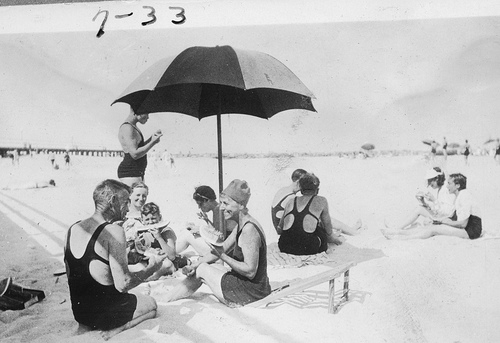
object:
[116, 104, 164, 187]
person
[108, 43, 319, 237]
umbrella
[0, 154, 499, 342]
sand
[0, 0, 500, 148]
sky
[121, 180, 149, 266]
woman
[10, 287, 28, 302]
black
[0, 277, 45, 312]
cloth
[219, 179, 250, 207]
cap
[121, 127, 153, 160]
arm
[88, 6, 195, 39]
date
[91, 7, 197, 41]
ink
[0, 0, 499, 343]
photo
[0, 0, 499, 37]
border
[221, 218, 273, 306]
suit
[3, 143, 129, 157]
pier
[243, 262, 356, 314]
chair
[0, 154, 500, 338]
ground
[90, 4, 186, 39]
writing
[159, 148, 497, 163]
swimming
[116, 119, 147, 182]
costume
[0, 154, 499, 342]
sandy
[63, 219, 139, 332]
suits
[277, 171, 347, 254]
women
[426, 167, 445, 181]
visor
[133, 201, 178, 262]
boy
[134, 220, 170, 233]
melon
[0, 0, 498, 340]
scene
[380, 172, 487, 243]
sitting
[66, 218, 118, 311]
backs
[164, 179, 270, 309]
lady